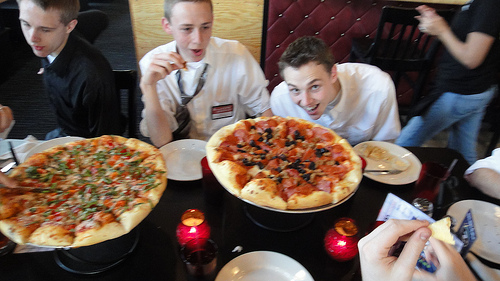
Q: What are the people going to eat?
A: Pizza.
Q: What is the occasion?
A: No indication.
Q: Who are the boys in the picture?
A: No indication.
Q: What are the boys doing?
A: Sitting down.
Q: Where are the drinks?
A: No indication.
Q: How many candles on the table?
A: Two.